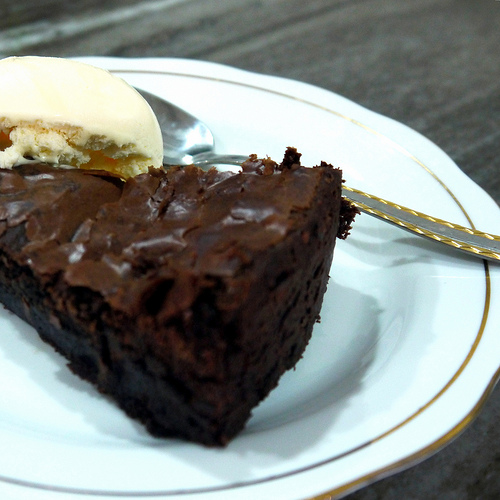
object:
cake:
[0, 145, 362, 450]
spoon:
[133, 86, 500, 265]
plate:
[0, 56, 500, 499]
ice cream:
[0, 54, 164, 180]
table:
[350, 0, 500, 105]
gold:
[464, 243, 500, 263]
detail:
[340, 184, 500, 263]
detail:
[132, 65, 295, 105]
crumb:
[337, 196, 362, 240]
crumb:
[278, 146, 302, 171]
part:
[309, 9, 486, 80]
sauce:
[25, 122, 150, 181]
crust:
[39, 173, 251, 256]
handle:
[160, 128, 500, 263]